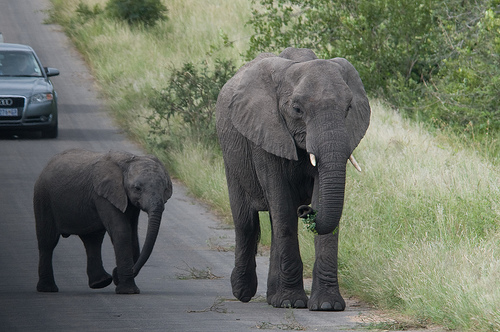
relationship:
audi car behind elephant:
[1, 33, 60, 139] [33, 147, 174, 294]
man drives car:
[7, 53, 41, 78] [4, 37, 64, 138]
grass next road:
[51, 0, 500, 332] [6, 45, 235, 329]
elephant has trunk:
[33, 147, 174, 294] [107, 207, 179, 294]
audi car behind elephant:
[1, 33, 60, 139] [210, 45, 370, 312]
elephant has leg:
[210, 45, 370, 312] [227, 200, 257, 300]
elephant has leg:
[266, 185, 314, 307] [269, 200, 309, 306]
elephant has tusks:
[215, 47, 371, 312] [303, 145, 370, 179]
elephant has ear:
[210, 45, 370, 312] [225, 56, 297, 163]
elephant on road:
[210, 45, 370, 312] [1, 1, 426, 330]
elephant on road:
[33, 147, 174, 294] [1, 1, 426, 330]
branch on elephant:
[302, 190, 349, 238] [231, 43, 388, 277]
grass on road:
[382, 183, 456, 266] [180, 188, 219, 249]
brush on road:
[146, 50, 198, 149] [180, 188, 219, 249]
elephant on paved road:
[210, 45, 370, 312] [0, 0, 432, 332]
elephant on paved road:
[33, 146, 181, 288] [0, 0, 432, 332]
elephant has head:
[210, 45, 370, 312] [226, 54, 372, 228]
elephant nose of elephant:
[298, 111, 349, 235] [204, 62, 306, 306]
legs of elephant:
[227, 220, 349, 313] [180, 32, 444, 318]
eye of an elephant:
[290, 102, 305, 118] [33, 147, 174, 294]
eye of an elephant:
[290, 102, 305, 118] [210, 45, 370, 312]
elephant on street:
[33, 147, 174, 294] [2, 144, 262, 326]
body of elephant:
[202, 58, 350, 223] [217, 49, 360, 312]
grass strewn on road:
[51, 0, 500, 332] [1, 1, 426, 330]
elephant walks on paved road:
[33, 147, 174, 294] [0, 0, 432, 332]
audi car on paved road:
[1, 33, 66, 138] [2, 3, 414, 328]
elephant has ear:
[210, 45, 370, 312] [335, 50, 374, 160]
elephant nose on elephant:
[307, 134, 363, 254] [197, 42, 387, 330]